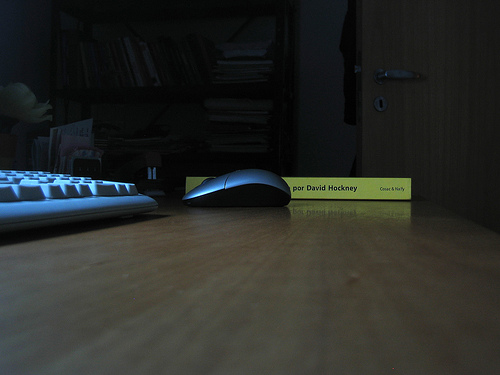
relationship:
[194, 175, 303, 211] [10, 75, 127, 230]
mouse of computer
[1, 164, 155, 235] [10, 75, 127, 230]
key pad for computer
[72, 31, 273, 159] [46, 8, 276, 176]
books on shelf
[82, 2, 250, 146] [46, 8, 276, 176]
documents on shelf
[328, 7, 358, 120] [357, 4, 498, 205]
jacket on door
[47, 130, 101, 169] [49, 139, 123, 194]
mail in holder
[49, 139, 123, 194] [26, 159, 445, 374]
holder on desk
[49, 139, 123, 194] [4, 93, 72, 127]
holder with flower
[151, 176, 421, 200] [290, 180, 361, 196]
book by david hockney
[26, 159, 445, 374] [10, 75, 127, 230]
desk of computer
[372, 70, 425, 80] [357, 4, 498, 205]
handle on door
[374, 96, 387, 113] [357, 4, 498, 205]
keyhole on door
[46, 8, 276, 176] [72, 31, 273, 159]
shelf full of books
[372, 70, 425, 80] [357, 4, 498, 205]
handle of door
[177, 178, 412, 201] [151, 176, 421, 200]
spine of book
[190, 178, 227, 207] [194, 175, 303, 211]
clicker on mouse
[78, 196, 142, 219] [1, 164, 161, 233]
edge of key pad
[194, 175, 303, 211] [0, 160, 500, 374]
mouse on desk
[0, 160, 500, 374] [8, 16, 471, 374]
desk in room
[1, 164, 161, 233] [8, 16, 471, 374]
key pad in room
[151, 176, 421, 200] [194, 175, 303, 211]
book next to mouse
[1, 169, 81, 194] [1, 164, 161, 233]
keys on key pad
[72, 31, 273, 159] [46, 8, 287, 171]
books on shelf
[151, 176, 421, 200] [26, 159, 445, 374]
book laying on desk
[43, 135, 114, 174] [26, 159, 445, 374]
papers on desk